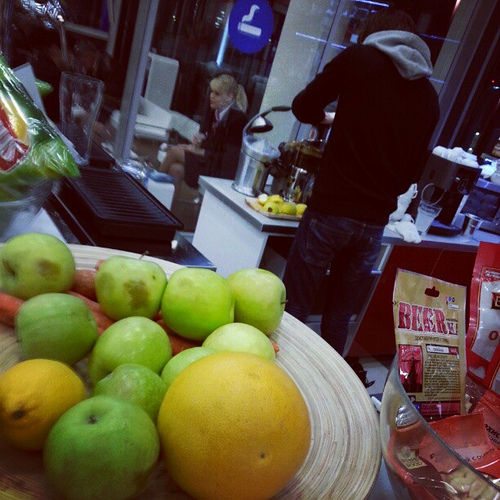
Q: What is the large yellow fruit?
A: Grapefruit.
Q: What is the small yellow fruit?
A: Lemon.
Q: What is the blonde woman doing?
A: Sitting.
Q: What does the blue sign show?
A: A cigarette.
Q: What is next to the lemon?
A: Apples.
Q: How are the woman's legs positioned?
A: Crossed.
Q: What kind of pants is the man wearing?
A: Jeans.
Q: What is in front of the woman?
A: Glass.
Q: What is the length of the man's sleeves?
A: Long.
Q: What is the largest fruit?
A: A grapefruit.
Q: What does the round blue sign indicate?
A: Smoking.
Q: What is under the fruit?
A: A white plate.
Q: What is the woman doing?
A: She is sitting.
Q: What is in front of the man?
A: Lemons.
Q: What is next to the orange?
A: A green apple.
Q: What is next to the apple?
A: A orange.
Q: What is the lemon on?
A: A plate.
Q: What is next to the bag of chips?
A: A grill.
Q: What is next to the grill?
A: Bag of Lays.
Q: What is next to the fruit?
A: A grill.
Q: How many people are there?
A: Two.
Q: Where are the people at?
A: Inside a building.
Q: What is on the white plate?
A: Fruit.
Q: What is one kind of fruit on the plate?
A: Apples.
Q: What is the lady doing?
A: Sitting down.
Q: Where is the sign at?
A: On the door.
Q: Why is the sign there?
A: To indicate smoking section.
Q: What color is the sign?
A: Blue and White.